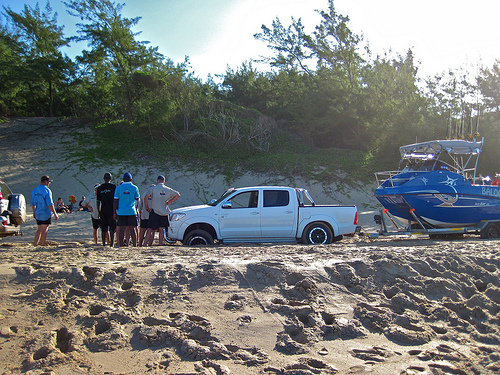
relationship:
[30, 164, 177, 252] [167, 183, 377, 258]
people standing by truck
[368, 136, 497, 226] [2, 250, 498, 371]
boat on sand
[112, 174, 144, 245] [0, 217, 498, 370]
man standing on beach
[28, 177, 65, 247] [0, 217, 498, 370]
man standing on beach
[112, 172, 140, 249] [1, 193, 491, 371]
man standing on beach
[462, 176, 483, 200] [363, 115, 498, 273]
letters on side of boat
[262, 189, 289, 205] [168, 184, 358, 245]
window on pickup truck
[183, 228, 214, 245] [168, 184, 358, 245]
tire of pickup truck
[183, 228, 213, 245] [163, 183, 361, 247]
tire of vehicle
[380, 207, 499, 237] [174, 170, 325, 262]
trailer attached to truck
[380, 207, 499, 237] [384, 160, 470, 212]
trailer carrying boat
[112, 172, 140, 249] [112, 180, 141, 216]
man in blue shirt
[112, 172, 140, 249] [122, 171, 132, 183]
man in baseball cap